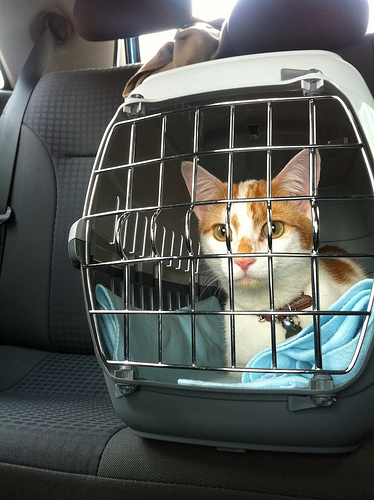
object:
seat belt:
[0, 22, 60, 262]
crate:
[69, 49, 374, 454]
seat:
[0, 31, 374, 500]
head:
[179, 145, 322, 289]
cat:
[178, 146, 368, 380]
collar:
[246, 294, 310, 331]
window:
[138, 0, 235, 70]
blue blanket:
[239, 278, 373, 390]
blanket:
[93, 283, 242, 389]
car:
[0, 0, 374, 500]